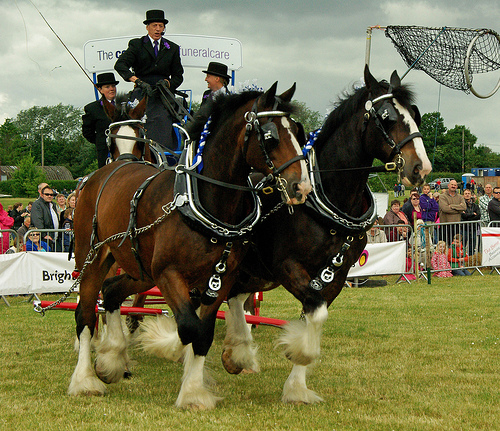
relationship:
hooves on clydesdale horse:
[64, 369, 115, 408] [64, 77, 332, 416]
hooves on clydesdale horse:
[95, 345, 132, 386] [64, 77, 332, 416]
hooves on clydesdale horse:
[171, 383, 225, 415] [64, 77, 332, 416]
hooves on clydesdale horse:
[174, 378, 218, 412] [64, 77, 332, 416]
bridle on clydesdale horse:
[171, 127, 271, 245] [64, 77, 332, 416]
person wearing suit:
[79, 70, 131, 170] [81, 97, 135, 166]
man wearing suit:
[115, 2, 188, 154] [114, 31, 187, 94]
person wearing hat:
[179, 59, 240, 154] [201, 59, 233, 88]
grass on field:
[6, 259, 497, 427] [0, 275, 500, 425]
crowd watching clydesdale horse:
[366, 173, 497, 280] [64, 77, 332, 416]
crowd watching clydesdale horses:
[366, 173, 497, 280] [132, 61, 437, 410]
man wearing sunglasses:
[26, 182, 63, 257] [37, 188, 53, 203]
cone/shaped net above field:
[382, 23, 500, 100] [4, 275, 497, 425]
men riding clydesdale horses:
[75, 7, 232, 166] [52, 66, 437, 410]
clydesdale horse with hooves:
[64, 82, 328, 412] [174, 378, 218, 412]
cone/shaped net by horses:
[382, 20, 484, 98] [62, 60, 435, 409]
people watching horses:
[2, 182, 76, 247] [62, 60, 435, 409]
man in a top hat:
[113, 6, 186, 166] [144, 6, 170, 27]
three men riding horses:
[81, 6, 249, 165] [62, 60, 435, 409]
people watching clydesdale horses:
[6, 174, 76, 245] [132, 61, 437, 410]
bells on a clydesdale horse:
[202, 238, 230, 308] [64, 77, 332, 416]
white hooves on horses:
[62, 314, 340, 414] [62, 60, 435, 409]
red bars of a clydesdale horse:
[45, 275, 291, 336] [64, 77, 332, 416]